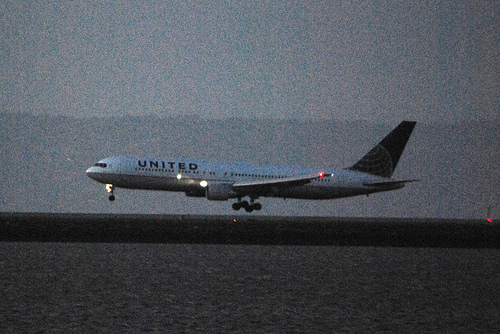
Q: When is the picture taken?
A: Night.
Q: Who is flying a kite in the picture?
A: No one.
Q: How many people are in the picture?
A: None.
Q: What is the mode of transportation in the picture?
A: Plane.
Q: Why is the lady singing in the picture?
A: She is not.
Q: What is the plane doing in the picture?
A: Landing.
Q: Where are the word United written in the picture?
A: On the side of the plane.